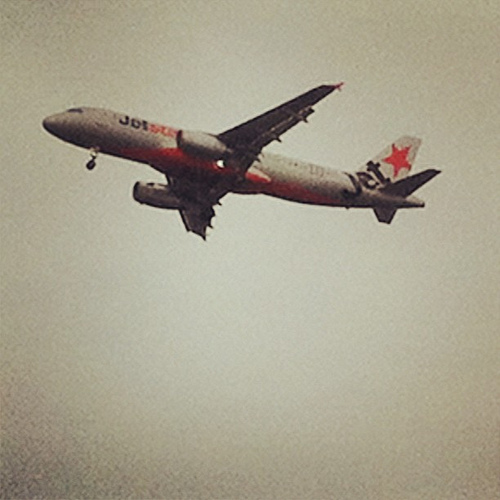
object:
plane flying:
[39, 79, 448, 245]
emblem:
[340, 142, 414, 202]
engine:
[173, 125, 241, 164]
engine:
[130, 181, 195, 213]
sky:
[2, 1, 499, 498]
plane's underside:
[58, 131, 413, 208]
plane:
[40, 81, 442, 244]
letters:
[338, 169, 364, 201]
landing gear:
[84, 143, 101, 171]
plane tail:
[359, 131, 442, 228]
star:
[382, 140, 413, 177]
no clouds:
[3, 0, 496, 495]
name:
[115, 111, 180, 141]